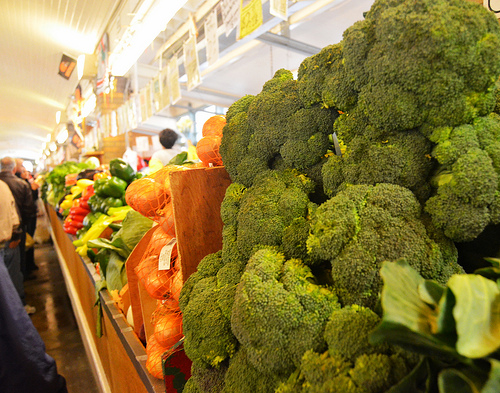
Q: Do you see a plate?
A: No, there are no plates.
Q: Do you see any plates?
A: No, there are no plates.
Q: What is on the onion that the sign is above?
A: The label is on the onion.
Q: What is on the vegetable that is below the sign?
A: The label is on the onion.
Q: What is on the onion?
A: The label is on the onion.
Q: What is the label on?
A: The label is on the onion.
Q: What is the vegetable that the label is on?
A: The vegetable is an onion.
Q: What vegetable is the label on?
A: The label is on the onion.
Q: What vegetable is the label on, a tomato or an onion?
A: The label is on an onion.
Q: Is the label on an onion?
A: Yes, the label is on an onion.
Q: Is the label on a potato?
A: No, the label is on an onion.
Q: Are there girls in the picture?
A: No, there are no girls.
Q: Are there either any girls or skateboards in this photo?
A: No, there are no girls or skateboards.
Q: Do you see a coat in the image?
A: Yes, there is a coat.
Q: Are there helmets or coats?
A: Yes, there is a coat.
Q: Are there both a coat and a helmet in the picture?
A: No, there is a coat but no helmets.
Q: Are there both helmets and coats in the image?
A: No, there is a coat but no helmets.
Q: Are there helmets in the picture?
A: No, there are no helmets.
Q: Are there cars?
A: No, there are no cars.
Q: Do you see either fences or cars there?
A: No, there are no cars or fences.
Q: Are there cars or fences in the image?
A: No, there are no cars or fences.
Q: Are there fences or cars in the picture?
A: No, there are no cars or fences.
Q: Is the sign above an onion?
A: Yes, the sign is above an onion.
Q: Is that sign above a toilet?
A: No, the sign is above an onion.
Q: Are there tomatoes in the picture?
A: No, there are no tomatoes.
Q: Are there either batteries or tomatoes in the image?
A: No, there are no tomatoes or batteries.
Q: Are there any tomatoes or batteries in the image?
A: No, there are no tomatoes or batteries.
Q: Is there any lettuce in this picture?
A: Yes, there is lettuce.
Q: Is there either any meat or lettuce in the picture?
A: Yes, there is lettuce.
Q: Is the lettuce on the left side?
A: Yes, the lettuce is on the left of the image.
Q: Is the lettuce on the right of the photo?
A: No, the lettuce is on the left of the image.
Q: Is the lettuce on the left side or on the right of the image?
A: The lettuce is on the left of the image.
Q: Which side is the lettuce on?
A: The lettuce is on the left of the image.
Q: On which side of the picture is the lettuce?
A: The lettuce is on the left of the image.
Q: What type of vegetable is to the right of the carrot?
A: The vegetable is lettuce.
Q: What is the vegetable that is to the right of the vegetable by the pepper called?
A: The vegetable is lettuce.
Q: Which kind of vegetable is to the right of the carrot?
A: The vegetable is lettuce.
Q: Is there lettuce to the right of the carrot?
A: Yes, there is lettuce to the right of the carrot.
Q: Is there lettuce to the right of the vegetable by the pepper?
A: Yes, there is lettuce to the right of the carrot.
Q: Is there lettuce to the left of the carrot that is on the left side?
A: No, the lettuce is to the right of the carrot.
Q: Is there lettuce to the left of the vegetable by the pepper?
A: No, the lettuce is to the right of the carrot.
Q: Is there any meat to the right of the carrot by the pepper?
A: No, there is lettuce to the right of the carrot.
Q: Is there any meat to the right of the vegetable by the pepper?
A: No, there is lettuce to the right of the carrot.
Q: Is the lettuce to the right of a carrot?
A: Yes, the lettuce is to the right of a carrot.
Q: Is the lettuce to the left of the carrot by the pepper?
A: No, the lettuce is to the right of the carrot.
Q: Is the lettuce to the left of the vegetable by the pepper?
A: No, the lettuce is to the right of the carrot.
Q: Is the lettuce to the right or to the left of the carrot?
A: The lettuce is to the right of the carrot.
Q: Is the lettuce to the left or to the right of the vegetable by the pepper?
A: The lettuce is to the right of the carrot.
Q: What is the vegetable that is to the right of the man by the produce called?
A: The vegetable is lettuce.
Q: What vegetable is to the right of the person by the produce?
A: The vegetable is lettuce.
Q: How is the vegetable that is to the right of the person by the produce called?
A: The vegetable is lettuce.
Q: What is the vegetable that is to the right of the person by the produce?
A: The vegetable is lettuce.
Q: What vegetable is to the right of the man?
A: The vegetable is lettuce.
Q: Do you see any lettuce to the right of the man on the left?
A: Yes, there is lettuce to the right of the man.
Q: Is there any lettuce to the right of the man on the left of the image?
A: Yes, there is lettuce to the right of the man.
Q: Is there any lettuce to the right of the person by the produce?
A: Yes, there is lettuce to the right of the man.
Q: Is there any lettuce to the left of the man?
A: No, the lettuce is to the right of the man.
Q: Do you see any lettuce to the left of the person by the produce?
A: No, the lettuce is to the right of the man.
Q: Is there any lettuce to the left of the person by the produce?
A: No, the lettuce is to the right of the man.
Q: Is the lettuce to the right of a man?
A: Yes, the lettuce is to the right of a man.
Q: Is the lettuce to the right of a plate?
A: No, the lettuce is to the right of a man.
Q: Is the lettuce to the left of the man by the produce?
A: No, the lettuce is to the right of the man.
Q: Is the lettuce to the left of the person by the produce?
A: No, the lettuce is to the right of the man.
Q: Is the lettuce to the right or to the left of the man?
A: The lettuce is to the right of the man.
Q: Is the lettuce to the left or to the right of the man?
A: The lettuce is to the right of the man.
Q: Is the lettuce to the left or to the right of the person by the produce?
A: The lettuce is to the right of the man.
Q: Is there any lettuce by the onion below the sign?
A: Yes, there is lettuce by the onion.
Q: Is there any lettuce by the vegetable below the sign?
A: Yes, there is lettuce by the onion.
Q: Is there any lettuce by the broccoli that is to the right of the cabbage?
A: Yes, there is lettuce by the broccoli.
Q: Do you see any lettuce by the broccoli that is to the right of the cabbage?
A: Yes, there is lettuce by the broccoli.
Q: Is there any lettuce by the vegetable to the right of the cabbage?
A: Yes, there is lettuce by the broccoli.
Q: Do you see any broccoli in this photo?
A: Yes, there is broccoli.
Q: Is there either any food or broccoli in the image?
A: Yes, there is broccoli.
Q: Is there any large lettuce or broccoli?
A: Yes, there is large broccoli.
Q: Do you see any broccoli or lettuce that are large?
A: Yes, the broccoli is large.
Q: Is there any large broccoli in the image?
A: Yes, there is large broccoli.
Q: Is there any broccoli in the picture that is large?
A: Yes, there is broccoli that is large.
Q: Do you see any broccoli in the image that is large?
A: Yes, there is broccoli that is large.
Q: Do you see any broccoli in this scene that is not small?
A: Yes, there is large broccoli.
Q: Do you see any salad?
A: No, there is no salad.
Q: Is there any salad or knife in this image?
A: No, there are no salad or knives.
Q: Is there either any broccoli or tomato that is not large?
A: No, there is broccoli but it is large.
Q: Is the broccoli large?
A: Yes, the broccoli is large.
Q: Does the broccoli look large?
A: Yes, the broccoli is large.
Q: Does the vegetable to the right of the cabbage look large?
A: Yes, the broccoli is large.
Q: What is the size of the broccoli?
A: The broccoli is large.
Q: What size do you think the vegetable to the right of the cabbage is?
A: The broccoli is large.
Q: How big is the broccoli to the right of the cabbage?
A: The broccoli is large.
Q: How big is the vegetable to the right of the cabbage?
A: The broccoli is large.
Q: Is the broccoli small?
A: No, the broccoli is large.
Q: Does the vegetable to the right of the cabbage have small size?
A: No, the broccoli is large.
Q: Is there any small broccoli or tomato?
A: No, there is broccoli but it is large.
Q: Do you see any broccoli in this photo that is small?
A: No, there is broccoli but it is large.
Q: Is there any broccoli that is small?
A: No, there is broccoli but it is large.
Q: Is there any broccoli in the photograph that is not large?
A: No, there is broccoli but it is large.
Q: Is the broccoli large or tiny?
A: The broccoli is large.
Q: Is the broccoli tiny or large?
A: The broccoli is large.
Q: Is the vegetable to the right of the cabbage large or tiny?
A: The broccoli is large.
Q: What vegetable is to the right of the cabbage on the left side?
A: The vegetable is broccoli.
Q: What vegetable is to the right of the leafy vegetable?
A: The vegetable is broccoli.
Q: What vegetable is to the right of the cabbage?
A: The vegetable is broccoli.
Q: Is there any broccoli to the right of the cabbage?
A: Yes, there is broccoli to the right of the cabbage.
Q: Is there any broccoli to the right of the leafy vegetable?
A: Yes, there is broccoli to the right of the cabbage.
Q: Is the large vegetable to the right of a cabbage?
A: Yes, the broccoli is to the right of a cabbage.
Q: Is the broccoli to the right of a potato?
A: No, the broccoli is to the right of a cabbage.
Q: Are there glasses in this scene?
A: No, there are no glasses.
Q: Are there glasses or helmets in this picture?
A: No, there are no glasses or helmets.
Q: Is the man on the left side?
A: Yes, the man is on the left of the image.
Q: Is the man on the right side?
A: No, the man is on the left of the image.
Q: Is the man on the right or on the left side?
A: The man is on the left of the image.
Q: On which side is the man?
A: The man is on the left of the image.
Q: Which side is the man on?
A: The man is on the left of the image.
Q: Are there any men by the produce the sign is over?
A: Yes, there is a man by the produce.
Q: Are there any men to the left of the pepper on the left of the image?
A: Yes, there is a man to the left of the pepper.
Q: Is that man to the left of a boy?
A: No, the man is to the left of the pepper.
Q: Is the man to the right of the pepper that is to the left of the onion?
A: No, the man is to the left of the pepper.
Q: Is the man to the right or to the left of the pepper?
A: The man is to the left of the pepper.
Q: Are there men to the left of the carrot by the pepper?
A: Yes, there is a man to the left of the carrot.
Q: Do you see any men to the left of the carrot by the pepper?
A: Yes, there is a man to the left of the carrot.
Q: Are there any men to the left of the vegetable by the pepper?
A: Yes, there is a man to the left of the carrot.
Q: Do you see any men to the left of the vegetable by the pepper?
A: Yes, there is a man to the left of the carrot.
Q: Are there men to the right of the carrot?
A: No, the man is to the left of the carrot.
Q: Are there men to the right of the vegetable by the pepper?
A: No, the man is to the left of the carrot.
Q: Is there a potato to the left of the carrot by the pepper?
A: No, there is a man to the left of the carrot.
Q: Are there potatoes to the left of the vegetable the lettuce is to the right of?
A: No, there is a man to the left of the carrot.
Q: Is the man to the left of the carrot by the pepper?
A: Yes, the man is to the left of the carrot.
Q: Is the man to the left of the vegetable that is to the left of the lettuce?
A: Yes, the man is to the left of the carrot.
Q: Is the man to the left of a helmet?
A: No, the man is to the left of the carrot.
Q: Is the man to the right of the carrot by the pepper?
A: No, the man is to the left of the carrot.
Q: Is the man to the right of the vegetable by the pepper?
A: No, the man is to the left of the carrot.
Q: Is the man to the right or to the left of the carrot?
A: The man is to the left of the carrot.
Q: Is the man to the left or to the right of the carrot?
A: The man is to the left of the carrot.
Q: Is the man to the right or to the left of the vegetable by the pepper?
A: The man is to the left of the carrot.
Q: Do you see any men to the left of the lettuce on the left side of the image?
A: Yes, there is a man to the left of the lettuce.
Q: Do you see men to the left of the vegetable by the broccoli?
A: Yes, there is a man to the left of the lettuce.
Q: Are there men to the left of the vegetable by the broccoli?
A: Yes, there is a man to the left of the lettuce.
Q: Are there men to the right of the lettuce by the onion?
A: No, the man is to the left of the lettuce.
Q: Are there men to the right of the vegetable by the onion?
A: No, the man is to the left of the lettuce.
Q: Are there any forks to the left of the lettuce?
A: No, there is a man to the left of the lettuce.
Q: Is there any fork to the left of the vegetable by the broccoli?
A: No, there is a man to the left of the lettuce.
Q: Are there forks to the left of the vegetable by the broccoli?
A: No, there is a man to the left of the lettuce.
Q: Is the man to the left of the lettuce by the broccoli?
A: Yes, the man is to the left of the lettuce.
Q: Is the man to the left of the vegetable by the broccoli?
A: Yes, the man is to the left of the lettuce.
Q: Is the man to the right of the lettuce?
A: No, the man is to the left of the lettuce.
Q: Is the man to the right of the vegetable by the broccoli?
A: No, the man is to the left of the lettuce.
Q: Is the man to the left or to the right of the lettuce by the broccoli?
A: The man is to the left of the lettuce.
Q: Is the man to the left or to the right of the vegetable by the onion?
A: The man is to the left of the lettuce.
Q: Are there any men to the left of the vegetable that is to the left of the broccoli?
A: Yes, there is a man to the left of the cabbage.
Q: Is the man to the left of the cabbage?
A: Yes, the man is to the left of the cabbage.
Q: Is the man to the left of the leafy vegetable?
A: Yes, the man is to the left of the cabbage.